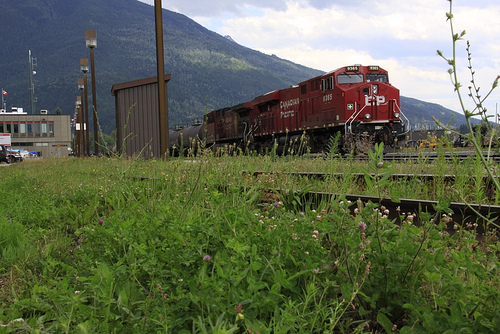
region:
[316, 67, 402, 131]
red and white engine of train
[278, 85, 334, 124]
red and white engine of train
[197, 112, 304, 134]
red and white engine of train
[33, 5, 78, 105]
green grass on side of mountain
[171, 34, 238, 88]
green grass on side of mountain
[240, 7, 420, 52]
gray and white clouds against blue sky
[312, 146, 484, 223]
green grass near gray metal train tracks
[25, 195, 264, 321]
long green grass near train tracks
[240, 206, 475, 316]
long green grass near train tracks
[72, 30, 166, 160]
brown light posts near train tracks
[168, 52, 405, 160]
a red train on the tracks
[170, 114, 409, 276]
wildflowers along the tracks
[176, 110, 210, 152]
a tanker truck on a train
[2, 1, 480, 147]
a mountain in the distance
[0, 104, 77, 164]
a concrete building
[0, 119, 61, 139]
a row of windows in a building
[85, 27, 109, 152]
a brown light post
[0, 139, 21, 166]
a vehicle parked near a building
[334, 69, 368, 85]
a front window on a train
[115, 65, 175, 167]
a shack on the side of the train tracks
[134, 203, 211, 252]
grass near the tracks.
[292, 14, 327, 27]
clouds in the sky.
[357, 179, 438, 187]
weeds between train tracks.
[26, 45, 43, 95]
antenna on the building.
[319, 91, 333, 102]
white numbers on train.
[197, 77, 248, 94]
trees on the hill.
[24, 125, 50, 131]
windows on the building.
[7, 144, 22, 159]
vehicles in parking lot.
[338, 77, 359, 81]
windshield of the train.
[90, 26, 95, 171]
post near the tracks.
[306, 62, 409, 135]
red engine of moving train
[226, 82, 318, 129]
red engine of moving train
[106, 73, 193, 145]
brown wooden post near train tracks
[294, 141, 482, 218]
gray metal tracks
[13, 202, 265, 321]
long green weeds near train tracks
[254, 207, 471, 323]
long green weeds near train tracks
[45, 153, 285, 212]
long green weeds near train tracks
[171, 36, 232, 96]
mountain covered by green grass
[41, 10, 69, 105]
mountain covered by green grass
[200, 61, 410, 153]
red train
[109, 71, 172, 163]
brown and gray shed by railroad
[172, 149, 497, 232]
railroad tracks through the plants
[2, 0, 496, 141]
mountain in the background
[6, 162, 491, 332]
green and purple weeds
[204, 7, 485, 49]
clouds in the sky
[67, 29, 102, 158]
brown and white light poles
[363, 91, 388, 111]
white letters on the red train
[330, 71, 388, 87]
windshield on the train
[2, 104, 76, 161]
gray building with windows